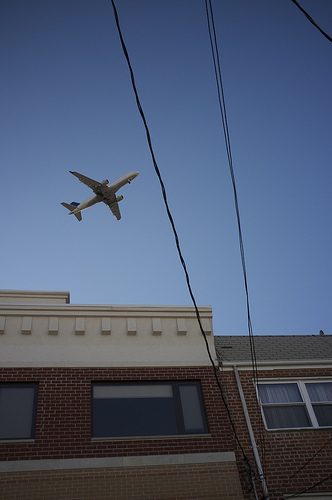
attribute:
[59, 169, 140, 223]
plane — large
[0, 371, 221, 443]
window frames — black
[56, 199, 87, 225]
fin — blue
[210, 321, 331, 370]
roof — grey, shingled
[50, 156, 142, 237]
plane — large, white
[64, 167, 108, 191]
wing — long, white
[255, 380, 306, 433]
windows — white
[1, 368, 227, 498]
wall — parapet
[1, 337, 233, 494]
building — brick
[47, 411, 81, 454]
brick — red